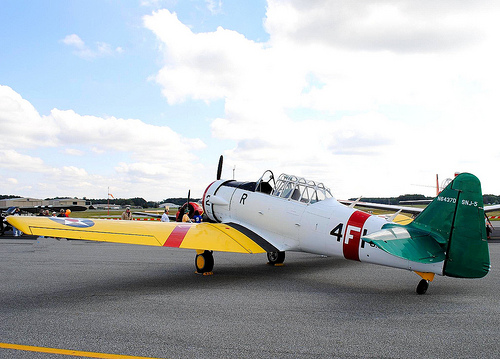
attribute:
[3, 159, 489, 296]
plane — rubber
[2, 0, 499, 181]
clouds — white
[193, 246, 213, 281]
wheel — black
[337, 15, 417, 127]
clouds — white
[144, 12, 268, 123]
clouds — white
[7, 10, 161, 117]
sky — blue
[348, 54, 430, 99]
clouds — white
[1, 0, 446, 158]
sky — cloudy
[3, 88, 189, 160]
cloud — white 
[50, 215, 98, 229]
circle — red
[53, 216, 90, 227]
star — white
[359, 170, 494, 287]
tail — green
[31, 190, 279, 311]
wings — yellow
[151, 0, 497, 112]
cloud — white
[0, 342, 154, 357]
line — yellow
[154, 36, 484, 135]
cloudy sky — light blue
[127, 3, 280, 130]
clouds — white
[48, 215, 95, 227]
circle — blue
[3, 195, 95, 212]
buildings — tan, small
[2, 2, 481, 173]
sky — blue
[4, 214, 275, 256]
wing — yellow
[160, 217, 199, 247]
stripe — red, diagonal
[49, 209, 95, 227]
circle — blue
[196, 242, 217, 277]
tire — black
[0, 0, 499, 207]
sky — blue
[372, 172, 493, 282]
tail — green